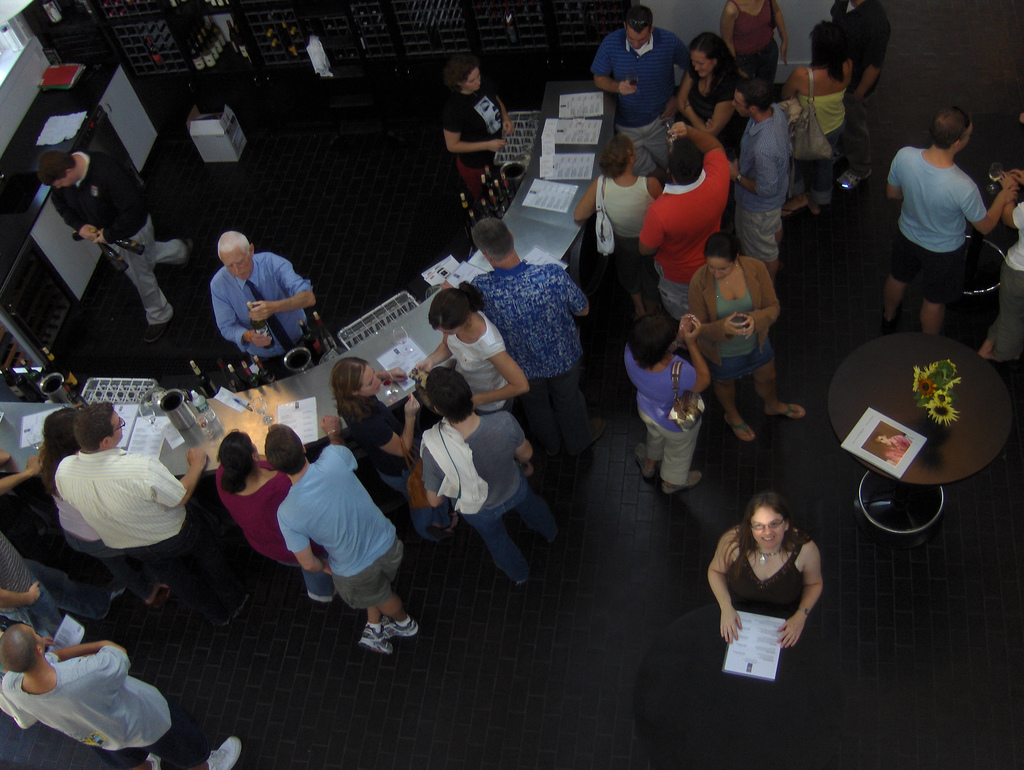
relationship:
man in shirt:
[203, 227, 326, 371] [208, 250, 314, 360]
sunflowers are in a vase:
[907, 355, 965, 434] [921, 401, 954, 434]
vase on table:
[921, 401, 954, 434] [825, 331, 1018, 554]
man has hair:
[203, 227, 326, 371] [216, 229, 250, 257]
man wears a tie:
[203, 227, 326, 371] [247, 275, 296, 358]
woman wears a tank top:
[705, 490, 827, 653] [724, 525, 809, 618]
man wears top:
[258, 410, 430, 662] [276, 441, 402, 583]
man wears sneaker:
[258, 410, 430, 662] [355, 621, 397, 659]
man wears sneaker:
[258, 410, 430, 662] [377, 615, 419, 639]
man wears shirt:
[203, 227, 326, 371] [208, 250, 314, 360]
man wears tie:
[203, 227, 326, 371] [247, 275, 296, 358]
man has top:
[258, 410, 430, 662] [276, 441, 402, 583]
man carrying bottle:
[31, 141, 207, 347] [100, 227, 151, 260]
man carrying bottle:
[31, 141, 207, 347] [97, 243, 127, 280]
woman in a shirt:
[208, 425, 317, 581] [213, 457, 309, 565]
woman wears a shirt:
[208, 425, 317, 581] [213, 457, 309, 565]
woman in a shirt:
[712, 0, 793, 96] [729, 0, 775, 55]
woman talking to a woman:
[712, 0, 793, 96] [827, 0, 893, 196]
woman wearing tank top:
[705, 490, 827, 653] [724, 525, 809, 618]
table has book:
[825, 331, 1018, 554] [834, 398, 931, 478]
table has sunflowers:
[825, 331, 1018, 554] [907, 355, 965, 434]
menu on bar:
[515, 177, 586, 218] [6, 71, 624, 498]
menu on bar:
[536, 147, 600, 185] [6, 71, 624, 498]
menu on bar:
[543, 116, 610, 150] [6, 71, 624, 498]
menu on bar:
[557, 88, 607, 122] [6, 71, 624, 498]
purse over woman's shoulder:
[590, 172, 620, 260] [579, 171, 617, 234]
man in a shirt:
[637, 114, 738, 327] [638, 146, 733, 290]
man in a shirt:
[453, 211, 604, 470] [469, 257, 591, 380]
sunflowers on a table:
[907, 355, 965, 434] [825, 331, 1018, 554]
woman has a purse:
[620, 307, 724, 503] [666, 356, 709, 437]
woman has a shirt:
[208, 425, 317, 581] [213, 457, 309, 565]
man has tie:
[203, 227, 326, 371] [247, 275, 296, 358]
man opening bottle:
[203, 227, 326, 371] [251, 303, 271, 348]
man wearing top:
[258, 410, 430, 662] [276, 441, 402, 583]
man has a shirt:
[868, 96, 1012, 349] [886, 135, 986, 260]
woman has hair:
[705, 490, 827, 653] [730, 486, 811, 579]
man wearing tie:
[203, 227, 326, 371] [247, 275, 296, 358]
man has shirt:
[637, 114, 738, 327] [638, 146, 733, 290]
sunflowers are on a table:
[907, 355, 965, 434] [825, 331, 1018, 554]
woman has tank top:
[705, 490, 827, 653] [724, 525, 809, 618]